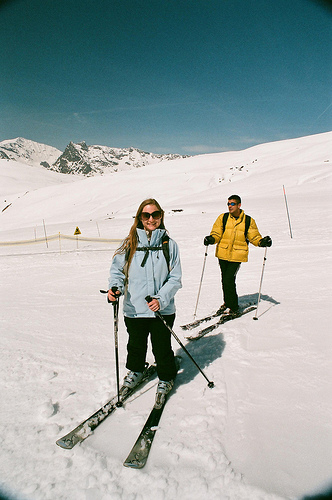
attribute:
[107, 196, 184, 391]
person — smiling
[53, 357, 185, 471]
skis — black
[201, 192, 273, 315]
person — looking, skiing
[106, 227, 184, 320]
jacket — blue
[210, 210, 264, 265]
jacket — yellow, puffy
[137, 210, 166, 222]
sunglasses — round, black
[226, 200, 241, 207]
sunglasses — black, blue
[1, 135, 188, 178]
mountains — rocky, distant, snowy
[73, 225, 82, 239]
sign — triangular, yellow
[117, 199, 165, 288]
hair — long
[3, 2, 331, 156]
sky — clear, cloudless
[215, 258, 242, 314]
pants — long, black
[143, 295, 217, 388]
ski pole — long, black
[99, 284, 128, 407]
ski pole — black, long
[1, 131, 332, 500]
snow — white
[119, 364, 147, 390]
boot — gray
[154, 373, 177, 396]
boot — gray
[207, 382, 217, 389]
tip — round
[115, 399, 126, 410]
tip — round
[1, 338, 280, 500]
area — disturbed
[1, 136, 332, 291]
area — smooth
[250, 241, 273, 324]
ski pole — silver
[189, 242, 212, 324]
ski pole — silver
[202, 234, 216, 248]
glove — black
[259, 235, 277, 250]
glove — black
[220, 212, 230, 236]
strap — black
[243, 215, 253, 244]
strap — black